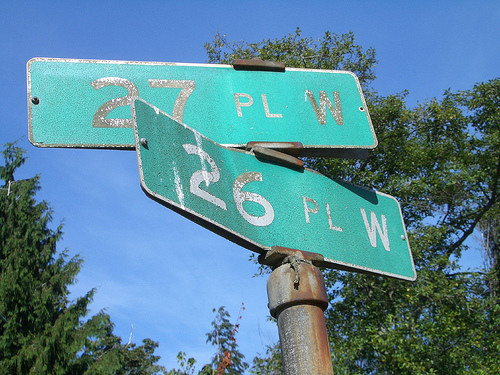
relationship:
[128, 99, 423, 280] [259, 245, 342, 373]
sign mounted on pole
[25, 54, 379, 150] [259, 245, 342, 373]
sign mounted on pole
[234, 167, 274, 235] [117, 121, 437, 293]
number on sign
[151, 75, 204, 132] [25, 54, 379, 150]
number on sign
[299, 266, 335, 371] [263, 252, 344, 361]
stain on pole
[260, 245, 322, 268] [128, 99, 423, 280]
metal tab on sign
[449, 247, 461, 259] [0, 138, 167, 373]
leaf on tree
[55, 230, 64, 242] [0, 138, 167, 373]
leaf on tree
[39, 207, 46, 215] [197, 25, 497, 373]
leaf on tree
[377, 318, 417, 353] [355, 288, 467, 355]
leaf on tree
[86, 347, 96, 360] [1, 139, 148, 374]
leaf on tree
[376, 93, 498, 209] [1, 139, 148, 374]
leaves on tree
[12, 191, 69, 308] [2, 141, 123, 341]
leaves on tree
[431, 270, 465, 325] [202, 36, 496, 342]
leaves on tree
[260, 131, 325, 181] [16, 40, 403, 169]
clips of sign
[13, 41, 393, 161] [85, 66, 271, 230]
sign has numbers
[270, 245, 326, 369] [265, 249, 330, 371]
rust on pole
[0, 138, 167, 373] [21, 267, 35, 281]
tree with leaves